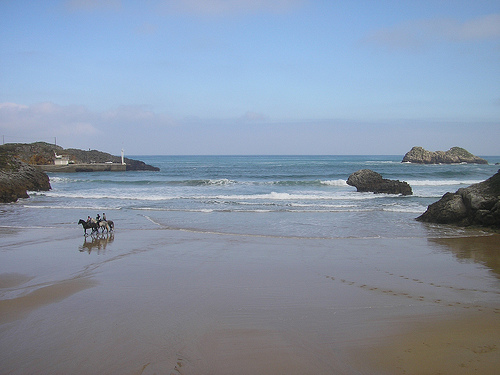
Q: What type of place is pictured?
A: It is a shore.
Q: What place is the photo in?
A: It is at the shore.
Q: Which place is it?
A: It is a shore.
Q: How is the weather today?
A: It is cloudy.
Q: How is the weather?
A: It is cloudy.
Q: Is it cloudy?
A: Yes, it is cloudy.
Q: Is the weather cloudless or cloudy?
A: It is cloudy.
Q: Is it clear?
A: No, it is cloudy.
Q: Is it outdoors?
A: Yes, it is outdoors.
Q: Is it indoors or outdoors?
A: It is outdoors.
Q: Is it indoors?
A: No, it is outdoors.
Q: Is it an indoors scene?
A: No, it is outdoors.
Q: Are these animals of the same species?
A: Yes, all the animals are horses.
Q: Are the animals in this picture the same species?
A: Yes, all the animals are horses.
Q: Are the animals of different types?
A: No, all the animals are horses.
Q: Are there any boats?
A: No, there are no boats.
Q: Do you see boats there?
A: No, there are no boats.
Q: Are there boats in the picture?
A: No, there are no boats.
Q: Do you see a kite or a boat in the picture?
A: No, there are no boats or kites.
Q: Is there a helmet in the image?
A: No, there are no helmets.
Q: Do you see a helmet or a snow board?
A: No, there are no helmets or snowboards.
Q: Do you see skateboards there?
A: No, there are no skateboards.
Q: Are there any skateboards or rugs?
A: No, there are no skateboards or rugs.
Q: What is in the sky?
A: The clouds are in the sky.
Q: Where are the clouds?
A: The clouds are in the sky.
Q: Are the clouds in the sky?
A: Yes, the clouds are in the sky.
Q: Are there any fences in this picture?
A: No, there are no fences.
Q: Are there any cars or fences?
A: No, there are no fences or cars.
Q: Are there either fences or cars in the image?
A: No, there are no fences or cars.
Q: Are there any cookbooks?
A: No, there are no cookbooks.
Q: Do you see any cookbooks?
A: No, there are no cookbooks.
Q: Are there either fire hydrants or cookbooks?
A: No, there are no cookbooks or fire hydrants.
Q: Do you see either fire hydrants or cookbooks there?
A: No, there are no cookbooks or fire hydrants.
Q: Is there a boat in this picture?
A: No, there are no boats.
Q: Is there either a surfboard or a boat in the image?
A: No, there are no boats or surfboards.